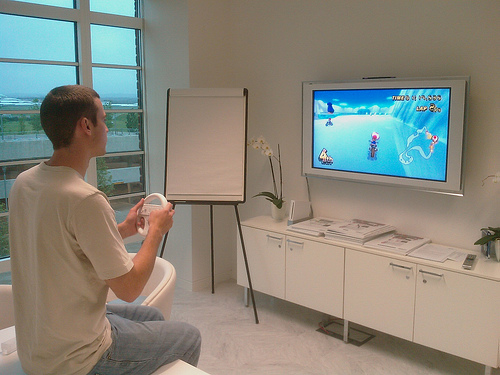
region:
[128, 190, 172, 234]
a white game controller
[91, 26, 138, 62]
a small window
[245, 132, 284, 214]
white and green flowers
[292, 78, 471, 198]
a large gray t.v.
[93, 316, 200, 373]
the leg of a boy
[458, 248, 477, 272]
a gray remote control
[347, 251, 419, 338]
a white cabinet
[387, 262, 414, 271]
a gray cabinet handle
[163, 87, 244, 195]
a large pad of white paper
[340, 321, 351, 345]
part of a silver drawer leg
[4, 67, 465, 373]
a boy playing a video game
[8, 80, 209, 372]
the boy is holding a white controller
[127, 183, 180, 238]
the controller is round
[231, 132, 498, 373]
white flowers on top of the cabinets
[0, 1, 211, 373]
windows beside the boy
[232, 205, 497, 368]
the cabinets have silver handles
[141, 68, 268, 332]
a presentation board beside the window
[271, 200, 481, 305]
papers on the cabinet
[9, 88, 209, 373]
the boy is wearing blue jeans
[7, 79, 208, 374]
the boy's shirt is white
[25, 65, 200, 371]
man wearing white shirt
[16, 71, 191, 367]
man wearing blue jeans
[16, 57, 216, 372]
man sitting on desk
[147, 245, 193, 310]
white chair in office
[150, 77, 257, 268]
paper on black easel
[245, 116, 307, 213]
flower on white shelf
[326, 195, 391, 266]
paper on white shelf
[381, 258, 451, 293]
handle on white door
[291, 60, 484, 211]
tv on white wall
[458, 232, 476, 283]
remote control on shelf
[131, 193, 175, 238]
Wii remote in a man's hands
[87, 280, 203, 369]
Blue jeans on a man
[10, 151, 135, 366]
Beige shirt on a man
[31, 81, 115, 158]
Brown hair on a man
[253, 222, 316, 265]
Silver handles on a cupboard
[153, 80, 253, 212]
Large, white paper pad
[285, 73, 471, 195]
TV on a wall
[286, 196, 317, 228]
Wii console on a shelf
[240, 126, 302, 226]
White flower by a TV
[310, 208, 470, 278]
Papers on a white shelf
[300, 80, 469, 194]
a wall mounted TV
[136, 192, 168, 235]
a Wii game controller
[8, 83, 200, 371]
a seated young man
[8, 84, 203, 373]
a man playing video game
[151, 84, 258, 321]
a three leg paper easel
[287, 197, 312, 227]
a white Wii game console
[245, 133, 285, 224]
a flower in white vase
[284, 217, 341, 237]
a stack of papers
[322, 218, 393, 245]
a stack of papers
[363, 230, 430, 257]
a stack of papers